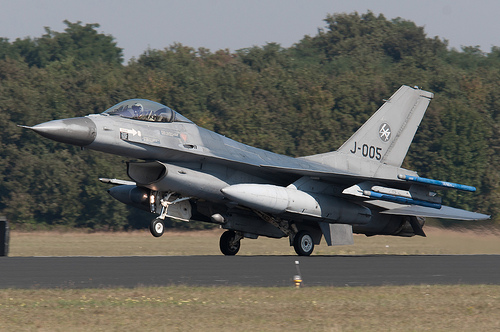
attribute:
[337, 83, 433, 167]
tail — gray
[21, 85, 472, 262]
aircraft — metal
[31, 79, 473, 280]
plane —  jet's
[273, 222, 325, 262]
wheel — white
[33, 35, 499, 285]
plane — jet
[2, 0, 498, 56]
sky — blue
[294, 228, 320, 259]
tire — black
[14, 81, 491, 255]
jet — a plane, small, gray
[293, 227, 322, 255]
wheel — pictured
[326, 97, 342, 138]
tree — old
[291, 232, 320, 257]
tire — rubber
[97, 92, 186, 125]
window — pictured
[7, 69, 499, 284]
plane —  jet's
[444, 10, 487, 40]
sky — blue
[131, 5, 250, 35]
clouds — white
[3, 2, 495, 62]
cloud — white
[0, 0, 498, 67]
cloud — white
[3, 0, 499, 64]
sky — blue, white